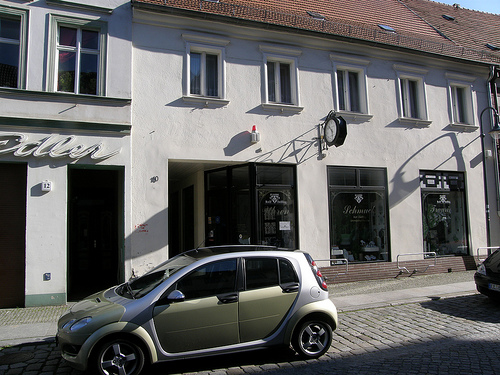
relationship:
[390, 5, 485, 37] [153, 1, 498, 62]
shingles are on roof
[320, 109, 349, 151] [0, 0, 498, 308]
clock in front of building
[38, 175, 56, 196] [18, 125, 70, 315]
number 12 on wall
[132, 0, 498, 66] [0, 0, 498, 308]
roof on building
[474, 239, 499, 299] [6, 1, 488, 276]
car in front of building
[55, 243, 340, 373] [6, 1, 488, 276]
car in front of building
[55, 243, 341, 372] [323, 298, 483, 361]
car on street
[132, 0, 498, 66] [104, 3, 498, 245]
roof on building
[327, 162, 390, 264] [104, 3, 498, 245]
window on building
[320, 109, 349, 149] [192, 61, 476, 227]
clock hanging from building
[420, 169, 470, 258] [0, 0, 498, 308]
window on building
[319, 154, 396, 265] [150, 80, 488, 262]
window on building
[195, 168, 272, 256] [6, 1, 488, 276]
doorway in building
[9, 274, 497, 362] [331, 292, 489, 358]
brick on street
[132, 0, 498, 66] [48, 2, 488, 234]
roof on building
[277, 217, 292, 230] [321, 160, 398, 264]
sign on window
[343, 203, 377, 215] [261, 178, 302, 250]
windowwriting on window